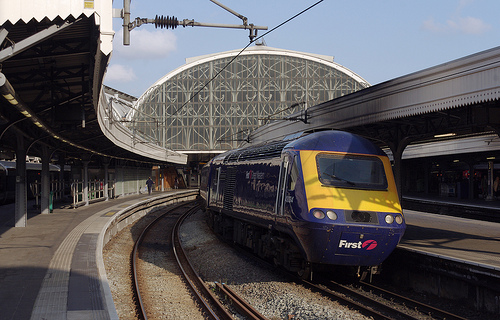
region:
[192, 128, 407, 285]
Dark blue and yellow train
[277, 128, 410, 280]
The word First on front of train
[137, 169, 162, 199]
Man wearing dark clothing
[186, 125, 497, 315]
Train parked beside platform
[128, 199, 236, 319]
Empty train tracks and gravel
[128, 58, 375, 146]
Arched, ornate metal structure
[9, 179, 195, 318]
Train station platform made of concrete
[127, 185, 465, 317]
Two side by side train tracks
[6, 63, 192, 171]
Metal awning and pole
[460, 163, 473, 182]
Small red and yellow light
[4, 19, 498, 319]
train station with blue and yellow train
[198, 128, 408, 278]
blue and yellow train in station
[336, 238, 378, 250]
logo on train in staion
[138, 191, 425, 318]
train track in train station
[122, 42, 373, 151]
large roud building behind station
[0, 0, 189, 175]
upper ceiling of train station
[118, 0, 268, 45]
electrical wire holder over station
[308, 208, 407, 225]
lights on train in station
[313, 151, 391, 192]
front window of train in station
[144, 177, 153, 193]
person walking on platform at station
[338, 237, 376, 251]
the word "First" in a large white on blue font with a stylized red logo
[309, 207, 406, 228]
small round train headlights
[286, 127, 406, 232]
yellow on blue painted front of train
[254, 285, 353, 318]
mixed gravel in sunlight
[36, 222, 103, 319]
light stone square patterned train loading zone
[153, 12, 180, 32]
metal electrical coil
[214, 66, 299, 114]
fancy stylized metal windows and frames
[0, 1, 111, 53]
white metal siding with sharp angled cut edges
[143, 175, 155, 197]
man walking along platform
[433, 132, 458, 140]
yellow indoor industrial ceiling light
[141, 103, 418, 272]
the train is blue with yellow window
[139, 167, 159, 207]
a person walking at the platform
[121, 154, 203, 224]
a person walking at the platform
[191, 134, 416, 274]
A blue and yellow train.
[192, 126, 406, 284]
A blue and gold train.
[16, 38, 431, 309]
A train at a depo.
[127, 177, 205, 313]
Metal train tracks.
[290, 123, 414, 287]
A train with headlights.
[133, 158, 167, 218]
A person on a train station platform.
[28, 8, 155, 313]
A platform for passengers.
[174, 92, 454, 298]
A blue and yellow passenger train.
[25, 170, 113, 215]
White metal rails.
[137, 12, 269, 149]
A metal pole with thick wire.